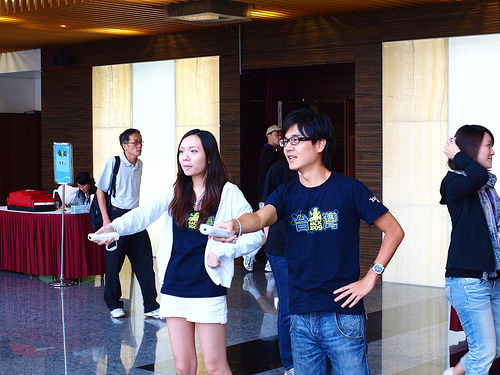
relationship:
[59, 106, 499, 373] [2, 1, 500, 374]
people in room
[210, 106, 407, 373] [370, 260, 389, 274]
man has watch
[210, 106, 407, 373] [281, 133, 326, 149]
man wearing spectacles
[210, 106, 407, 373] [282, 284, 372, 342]
man holding waist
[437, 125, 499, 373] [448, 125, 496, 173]
woman holding hair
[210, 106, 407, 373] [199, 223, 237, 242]
man holding remotes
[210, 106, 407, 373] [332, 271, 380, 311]
man has hand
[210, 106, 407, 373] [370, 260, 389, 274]
man wearing watch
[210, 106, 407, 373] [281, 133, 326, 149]
man has spectacles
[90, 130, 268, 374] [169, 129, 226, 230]
lady has hair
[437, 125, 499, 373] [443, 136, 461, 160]
woman has hand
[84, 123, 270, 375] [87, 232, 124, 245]
lady holding controller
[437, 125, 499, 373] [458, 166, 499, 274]
woman wearing scarf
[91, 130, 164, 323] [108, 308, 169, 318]
man with shoes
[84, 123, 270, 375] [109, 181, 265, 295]
lady wearing jacket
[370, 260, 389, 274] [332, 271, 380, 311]
watch in hand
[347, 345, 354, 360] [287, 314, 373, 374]
part of jeans